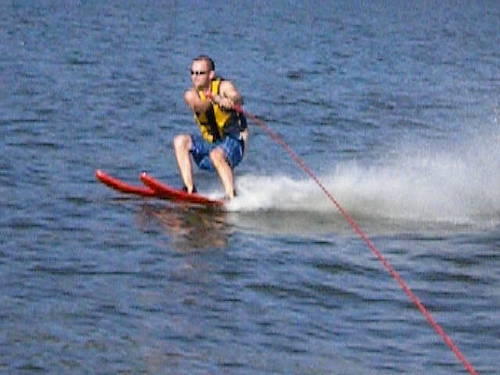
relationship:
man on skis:
[173, 55, 248, 201] [79, 160, 234, 229]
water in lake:
[0, 0, 500, 375] [214, 51, 451, 318]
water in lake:
[0, 0, 500, 375] [1, 2, 482, 369]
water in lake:
[0, 0, 500, 375] [110, 280, 222, 328]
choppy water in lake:
[91, 246, 379, 330] [66, 275, 148, 375]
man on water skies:
[173, 55, 248, 201] [135, 164, 186, 254]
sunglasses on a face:
[185, 64, 205, 160] [190, 60, 210, 87]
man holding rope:
[173, 55, 248, 201] [241, 101, 472, 372]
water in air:
[209, 125, 499, 239] [304, 139, 463, 281]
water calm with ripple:
[0, 0, 500, 375] [317, 258, 380, 279]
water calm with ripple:
[0, 0, 500, 375] [349, 343, 381, 356]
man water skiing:
[173, 55, 248, 201] [112, 158, 192, 311]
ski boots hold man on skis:
[204, 184, 224, 274] [129, 160, 158, 287]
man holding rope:
[173, 55, 248, 201] [225, 104, 492, 328]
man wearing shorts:
[173, 55, 248, 201] [157, 123, 271, 175]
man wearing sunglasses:
[173, 55, 248, 201] [189, 70, 210, 75]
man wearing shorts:
[173, 55, 248, 201] [185, 130, 244, 172]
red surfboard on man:
[95, 168, 223, 205] [173, 55, 248, 201]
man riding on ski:
[173, 55, 248, 201] [84, 161, 224, 211]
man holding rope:
[152, 39, 272, 186] [203, 93, 490, 373]